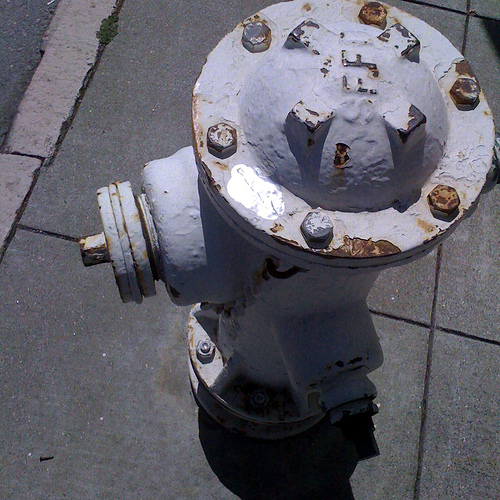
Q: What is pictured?
A: A fire hydrant.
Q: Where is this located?
A: On a sidewalk.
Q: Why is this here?
A: To help put out fires.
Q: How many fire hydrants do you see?
A: One.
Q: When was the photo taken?
A: Daylight hours.